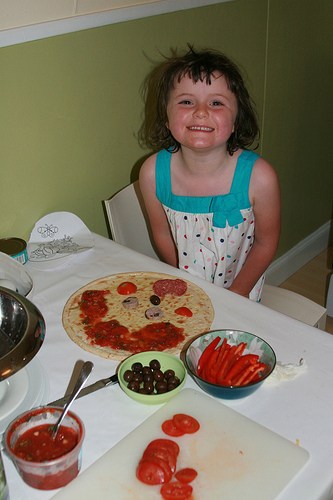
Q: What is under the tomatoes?
A: White cutting board.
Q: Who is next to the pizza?
A: Girl sitting on chair.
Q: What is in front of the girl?
A: Tortilla on the table.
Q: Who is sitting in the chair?
A: Girl with short brown hair.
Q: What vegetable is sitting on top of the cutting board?
A: Tomato.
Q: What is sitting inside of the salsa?
A: Utensil.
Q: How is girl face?
A: Smiling.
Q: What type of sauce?
A: Pizza.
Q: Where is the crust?
A: Pizza.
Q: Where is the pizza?
A: On table.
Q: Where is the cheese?
A: On pizza.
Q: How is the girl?
A: Happy.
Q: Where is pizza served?
A: Table.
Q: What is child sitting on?
A: Chair.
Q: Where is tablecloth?
A: On table.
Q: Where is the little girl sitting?
A: Chair.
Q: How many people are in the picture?
A: One.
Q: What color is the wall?
A: Green.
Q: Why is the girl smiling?
A: Happy.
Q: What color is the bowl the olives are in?
A: Green.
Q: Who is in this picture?
A: Little girl.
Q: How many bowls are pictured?
A: Four.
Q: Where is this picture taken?
A: At a table.